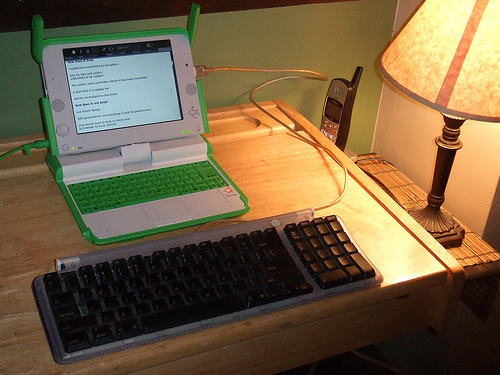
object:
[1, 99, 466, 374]
desk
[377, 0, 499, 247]
lamp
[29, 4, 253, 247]
laptop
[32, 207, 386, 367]
keyboard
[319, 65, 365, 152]
telephone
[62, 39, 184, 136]
screen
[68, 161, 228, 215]
keyboard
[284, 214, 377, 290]
number pad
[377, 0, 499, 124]
lamp shade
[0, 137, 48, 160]
wire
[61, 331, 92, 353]
key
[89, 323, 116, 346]
key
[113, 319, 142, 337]
key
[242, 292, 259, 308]
key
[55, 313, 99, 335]
key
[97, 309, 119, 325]
key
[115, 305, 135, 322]
key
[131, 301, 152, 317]
key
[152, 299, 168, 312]
key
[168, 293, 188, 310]
key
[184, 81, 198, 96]
speaker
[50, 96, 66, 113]
speaker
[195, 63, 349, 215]
cord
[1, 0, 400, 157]
wall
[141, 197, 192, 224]
touchpad